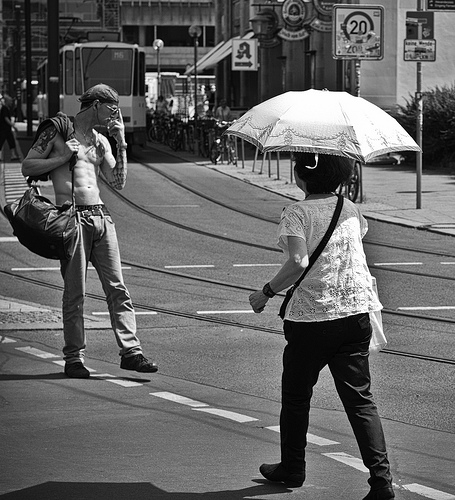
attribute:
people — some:
[13, 57, 454, 498]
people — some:
[3, 81, 160, 381]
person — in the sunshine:
[256, 152, 406, 498]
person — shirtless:
[247, 146, 398, 497]